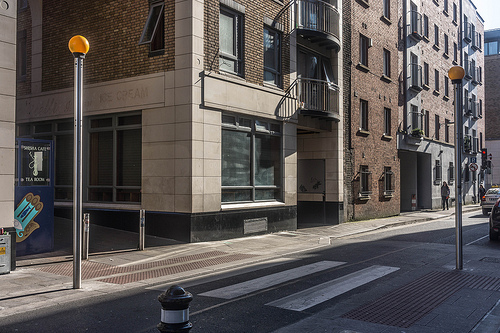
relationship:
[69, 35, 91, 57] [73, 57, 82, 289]
ball on top of pole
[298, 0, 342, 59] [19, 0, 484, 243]
balcony on apartment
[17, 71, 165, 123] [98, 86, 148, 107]
sign for ice cream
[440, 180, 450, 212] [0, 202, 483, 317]
woman walking on sidewalk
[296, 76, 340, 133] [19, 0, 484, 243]
balcony on apartment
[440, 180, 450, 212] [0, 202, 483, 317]
woman walking down sidewalk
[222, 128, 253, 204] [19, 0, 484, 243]
window on apartment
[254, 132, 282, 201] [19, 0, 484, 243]
window on apartment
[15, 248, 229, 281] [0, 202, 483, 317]
strip on sidewalk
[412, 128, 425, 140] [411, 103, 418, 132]
flowers on ledge of window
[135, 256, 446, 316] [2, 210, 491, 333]
crosswalk on street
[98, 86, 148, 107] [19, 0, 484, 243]
ice cream written on apartment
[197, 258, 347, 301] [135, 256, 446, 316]
line in crosswalk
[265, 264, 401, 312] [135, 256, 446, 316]
line in crosswalk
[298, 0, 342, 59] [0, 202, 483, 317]
balcony above sidewalk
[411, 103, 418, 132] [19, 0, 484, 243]
window on apartment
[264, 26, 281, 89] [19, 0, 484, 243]
window on apartment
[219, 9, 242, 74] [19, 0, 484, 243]
window on apartment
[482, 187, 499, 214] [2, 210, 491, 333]
car in street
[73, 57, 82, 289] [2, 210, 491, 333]
pole along street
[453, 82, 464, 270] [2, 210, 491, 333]
post along street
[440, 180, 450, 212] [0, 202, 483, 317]
person walking on sidewalk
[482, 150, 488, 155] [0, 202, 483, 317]
traffic-signal on sidewalk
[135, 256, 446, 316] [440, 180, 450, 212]
crosswalk for woman